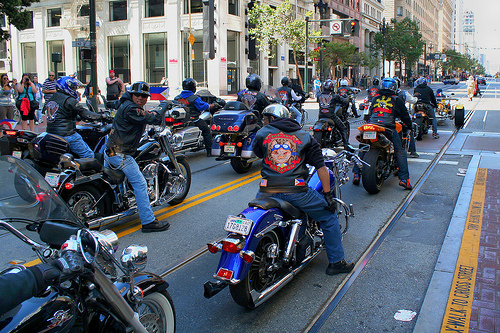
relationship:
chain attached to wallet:
[101, 150, 125, 171] [105, 150, 118, 156]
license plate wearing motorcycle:
[222, 214, 254, 235] [204, 140, 359, 327]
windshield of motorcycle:
[1, 152, 86, 227] [1, 153, 176, 331]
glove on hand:
[62, 249, 87, 273] [33, 252, 100, 299]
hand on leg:
[326, 190, 336, 210] [298, 186, 355, 276]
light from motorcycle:
[202, 237, 233, 264] [195, 144, 378, 319]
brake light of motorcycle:
[220, 238, 242, 255] [202, 147, 353, 308]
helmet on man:
[264, 100, 292, 123] [249, 103, 355, 277]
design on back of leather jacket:
[260, 131, 300, 173] [104, 101, 170, 155]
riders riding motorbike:
[252, 102, 356, 275] [201, 142, 371, 314]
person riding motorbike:
[101, 78, 172, 232] [37, 123, 194, 229]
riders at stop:
[252, 102, 355, 274] [13, 73, 496, 227]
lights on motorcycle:
[100, 224, 152, 273] [1, 209, 179, 328]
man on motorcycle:
[249, 103, 355, 277] [202, 165, 356, 310]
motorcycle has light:
[202, 147, 353, 308] [234, 245, 265, 270]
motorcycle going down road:
[202, 147, 353, 308] [2, 83, 497, 330]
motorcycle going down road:
[1, 153, 176, 331] [2, 83, 497, 330]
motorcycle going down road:
[351, 122, 412, 195] [2, 83, 497, 330]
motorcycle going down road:
[49, 124, 193, 233] [2, 83, 497, 330]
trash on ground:
[393, 308, 417, 323] [343, 176, 445, 326]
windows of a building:
[145, 30, 167, 88] [2, 0, 329, 106]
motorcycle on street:
[49, 124, 193, 233] [37, 78, 399, 328]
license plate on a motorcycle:
[222, 214, 254, 235] [202, 147, 353, 308]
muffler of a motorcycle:
[249, 264, 322, 309] [195, 144, 378, 319]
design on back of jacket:
[260, 130, 301, 173] [39, 92, 84, 134]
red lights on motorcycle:
[210, 218, 250, 258] [202, 147, 353, 308]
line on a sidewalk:
[439, 167, 489, 331] [409, 154, 499, 331]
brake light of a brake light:
[220, 237, 242, 255] [362, 123, 379, 132]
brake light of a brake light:
[220, 237, 242, 255] [5, 128, 16, 135]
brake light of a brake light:
[220, 237, 242, 255] [313, 127, 322, 132]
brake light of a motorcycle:
[220, 237, 242, 255] [31, 117, 203, 249]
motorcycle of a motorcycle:
[49, 145, 198, 212] [353, 115, 409, 181]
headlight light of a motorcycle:
[121, 236, 153, 279] [353, 115, 409, 181]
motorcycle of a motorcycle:
[49, 124, 193, 233] [209, 157, 358, 308]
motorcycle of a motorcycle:
[355, 117, 422, 199] [209, 157, 358, 308]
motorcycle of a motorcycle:
[211, 100, 276, 167] [209, 157, 358, 308]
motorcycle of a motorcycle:
[168, 92, 228, 157] [209, 157, 358, 308]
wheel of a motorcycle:
[226, 222, 285, 311] [209, 157, 358, 308]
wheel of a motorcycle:
[158, 157, 193, 205] [209, 157, 358, 308]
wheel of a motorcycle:
[363, 145, 393, 197] [209, 157, 358, 308]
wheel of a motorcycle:
[228, 139, 254, 174] [209, 157, 358, 308]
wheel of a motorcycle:
[44, 177, 121, 232] [209, 157, 358, 308]